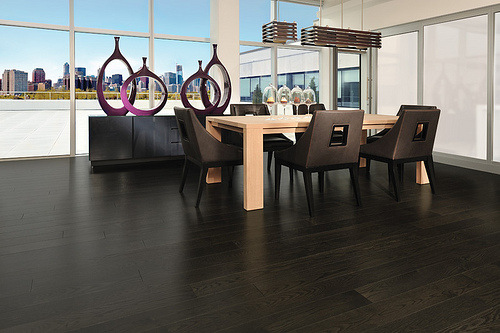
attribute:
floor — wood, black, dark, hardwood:
[3, 152, 500, 332]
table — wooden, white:
[203, 113, 435, 212]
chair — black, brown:
[270, 106, 367, 221]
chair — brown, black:
[358, 105, 438, 205]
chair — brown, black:
[171, 104, 251, 213]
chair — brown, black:
[231, 100, 297, 192]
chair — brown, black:
[369, 105, 439, 182]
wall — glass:
[326, 5, 499, 177]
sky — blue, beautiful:
[1, 2, 320, 92]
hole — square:
[327, 124, 350, 150]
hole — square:
[411, 120, 430, 143]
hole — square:
[178, 119, 192, 143]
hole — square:
[245, 110, 257, 116]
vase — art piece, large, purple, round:
[95, 35, 140, 117]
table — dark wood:
[85, 113, 247, 174]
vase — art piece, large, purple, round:
[119, 55, 171, 115]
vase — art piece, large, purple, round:
[182, 58, 223, 113]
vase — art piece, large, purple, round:
[201, 44, 234, 115]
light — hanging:
[262, 21, 299, 46]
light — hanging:
[300, 23, 383, 53]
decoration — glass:
[261, 81, 279, 116]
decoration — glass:
[276, 82, 293, 117]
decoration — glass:
[291, 81, 305, 117]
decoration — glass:
[301, 85, 317, 115]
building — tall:
[175, 62, 185, 92]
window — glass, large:
[73, 1, 153, 38]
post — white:
[69, 31, 77, 102]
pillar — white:
[208, 2, 241, 116]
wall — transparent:
[1, 1, 332, 120]